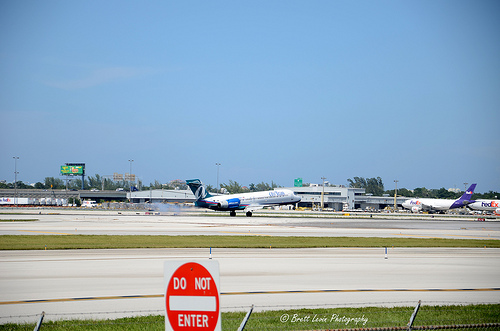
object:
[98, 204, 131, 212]
roof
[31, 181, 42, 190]
tree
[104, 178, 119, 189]
tree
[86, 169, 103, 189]
tree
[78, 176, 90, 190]
tree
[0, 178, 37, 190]
tree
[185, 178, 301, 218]
airplane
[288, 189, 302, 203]
plane tip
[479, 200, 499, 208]
logo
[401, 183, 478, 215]
plane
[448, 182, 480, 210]
purple tail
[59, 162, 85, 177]
sign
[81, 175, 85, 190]
pole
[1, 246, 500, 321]
run way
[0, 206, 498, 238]
run way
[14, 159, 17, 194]
post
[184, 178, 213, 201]
design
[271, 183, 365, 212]
terminal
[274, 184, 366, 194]
roof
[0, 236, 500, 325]
surface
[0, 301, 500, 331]
fence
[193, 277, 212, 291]
word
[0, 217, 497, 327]
road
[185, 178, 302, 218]
plane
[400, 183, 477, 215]
airplane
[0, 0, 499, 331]
air terminal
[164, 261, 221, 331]
sign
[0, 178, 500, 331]
airport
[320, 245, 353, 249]
edge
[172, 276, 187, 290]
word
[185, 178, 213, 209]
tail